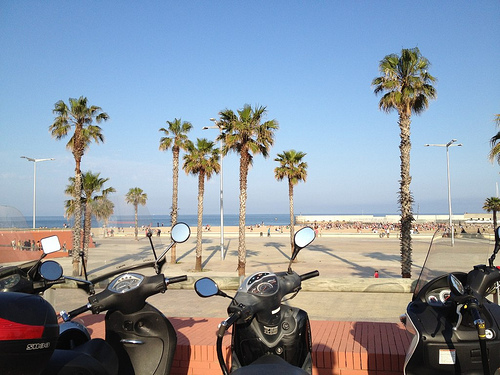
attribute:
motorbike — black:
[193, 226, 319, 373]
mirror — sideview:
[268, 214, 325, 271]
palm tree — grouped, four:
[49, 97, 113, 280]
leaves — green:
[45, 89, 115, 164]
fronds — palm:
[220, 106, 270, 181]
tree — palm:
[117, 193, 145, 243]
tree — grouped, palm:
[377, 47, 444, 274]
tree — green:
[216, 104, 281, 296]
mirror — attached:
[152, 220, 187, 274]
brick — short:
[338, 320, 399, 368]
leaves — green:
[148, 91, 199, 267]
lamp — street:
[13, 146, 57, 241]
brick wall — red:
[53, 310, 418, 373]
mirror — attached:
[285, 223, 323, 273]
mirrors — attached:
[35, 228, 60, 285]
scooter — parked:
[192, 226, 328, 373]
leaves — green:
[394, 43, 436, 77]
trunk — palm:
[398, 135, 417, 277]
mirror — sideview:
[38, 233, 60, 256]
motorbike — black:
[396, 236, 498, 373]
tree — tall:
[162, 75, 347, 232]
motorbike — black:
[188, 257, 318, 374]